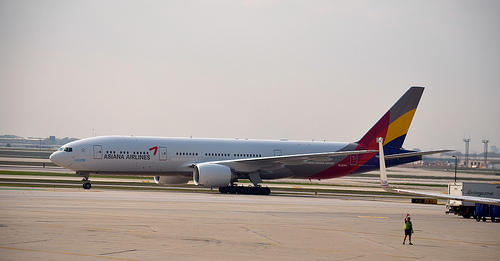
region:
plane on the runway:
[8, 75, 424, 215]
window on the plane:
[94, 144, 101, 161]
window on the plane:
[104, 149, 107, 156]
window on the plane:
[130, 146, 138, 158]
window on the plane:
[173, 147, 186, 160]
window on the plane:
[195, 148, 205, 160]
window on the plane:
[175, 150, 183, 160]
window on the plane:
[231, 152, 238, 162]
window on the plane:
[236, 148, 243, 156]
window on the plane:
[207, 148, 213, 158]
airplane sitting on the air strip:
[49, 87, 452, 192]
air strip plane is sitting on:
[0, 187, 497, 259]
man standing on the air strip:
[400, 212, 415, 243]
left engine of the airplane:
[191, 160, 231, 185]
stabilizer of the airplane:
[357, 86, 422, 146]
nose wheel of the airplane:
[76, 176, 89, 187]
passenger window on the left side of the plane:
[173, 148, 264, 158]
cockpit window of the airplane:
[53, 143, 73, 153]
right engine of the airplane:
[148, 172, 190, 183]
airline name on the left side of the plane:
[102, 152, 154, 162]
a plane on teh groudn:
[139, 54, 391, 256]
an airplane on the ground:
[78, 104, 297, 257]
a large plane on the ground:
[82, 109, 271, 223]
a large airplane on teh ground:
[98, 75, 276, 210]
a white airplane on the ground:
[34, 77, 286, 202]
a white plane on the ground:
[90, 86, 317, 215]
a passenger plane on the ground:
[69, 109, 264, 209]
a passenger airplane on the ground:
[18, 97, 246, 234]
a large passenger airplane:
[43, 116, 244, 191]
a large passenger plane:
[58, 116, 236, 214]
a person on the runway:
[402, 210, 414, 243]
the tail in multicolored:
[364, 84, 423, 154]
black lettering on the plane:
[103, 154, 148, 161]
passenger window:
[176, 151, 198, 155]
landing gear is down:
[81, 173, 92, 188]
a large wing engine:
[193, 163, 235, 185]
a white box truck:
[448, 181, 498, 210]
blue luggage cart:
[473, 203, 497, 222]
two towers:
[463, 136, 489, 166]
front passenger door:
[93, 145, 101, 157]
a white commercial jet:
[47, 83, 429, 200]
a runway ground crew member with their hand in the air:
[402, 207, 418, 249]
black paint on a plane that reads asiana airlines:
[96, 150, 162, 162]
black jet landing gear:
[214, 178, 274, 196]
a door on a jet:
[93, 140, 104, 161]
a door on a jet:
[157, 141, 171, 165]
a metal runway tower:
[459, 127, 475, 170]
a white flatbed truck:
[441, 175, 499, 217]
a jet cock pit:
[61, 143, 76, 155]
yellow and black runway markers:
[404, 190, 438, 205]